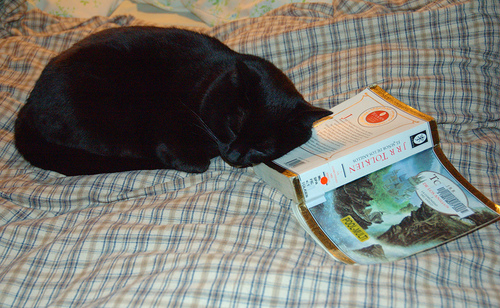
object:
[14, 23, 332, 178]
cat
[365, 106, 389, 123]
circle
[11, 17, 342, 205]
mammal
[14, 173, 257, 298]
bed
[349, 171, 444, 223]
waterfalls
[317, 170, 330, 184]
circle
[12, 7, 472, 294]
bed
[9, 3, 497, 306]
cot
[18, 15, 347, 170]
cat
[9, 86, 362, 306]
blanket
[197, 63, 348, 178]
head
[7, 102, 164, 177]
tail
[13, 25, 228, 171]
body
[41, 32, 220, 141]
fur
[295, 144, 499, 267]
cover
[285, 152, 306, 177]
barcode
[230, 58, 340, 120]
ears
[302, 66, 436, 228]
book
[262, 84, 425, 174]
cover book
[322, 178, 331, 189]
drop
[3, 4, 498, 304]
sheets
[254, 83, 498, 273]
novel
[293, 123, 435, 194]
spine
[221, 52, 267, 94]
ear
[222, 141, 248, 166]
nose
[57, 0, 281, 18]
light